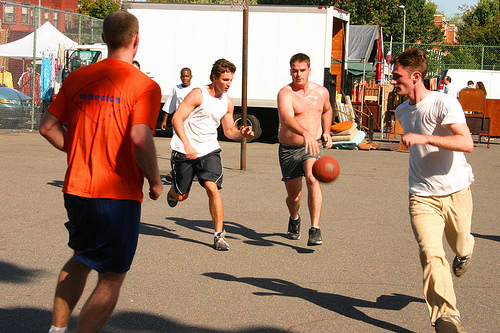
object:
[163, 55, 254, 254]
man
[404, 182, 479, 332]
pants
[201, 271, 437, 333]
shadow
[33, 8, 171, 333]
man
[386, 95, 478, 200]
tshirt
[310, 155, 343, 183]
ball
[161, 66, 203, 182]
dark man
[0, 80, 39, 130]
car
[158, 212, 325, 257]
shadow man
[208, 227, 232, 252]
tennis shoe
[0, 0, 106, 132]
fence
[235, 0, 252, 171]
pole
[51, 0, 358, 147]
lorry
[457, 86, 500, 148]
furniture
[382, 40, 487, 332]
man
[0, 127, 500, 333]
concrete floor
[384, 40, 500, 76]
fence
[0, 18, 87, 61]
tent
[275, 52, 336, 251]
man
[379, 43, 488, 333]
guy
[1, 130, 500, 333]
court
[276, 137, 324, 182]
shorts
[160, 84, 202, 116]
shirt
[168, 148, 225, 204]
shorts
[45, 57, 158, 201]
shirt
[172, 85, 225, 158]
tank top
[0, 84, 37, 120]
front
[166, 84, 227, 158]
vest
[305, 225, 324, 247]
shoe